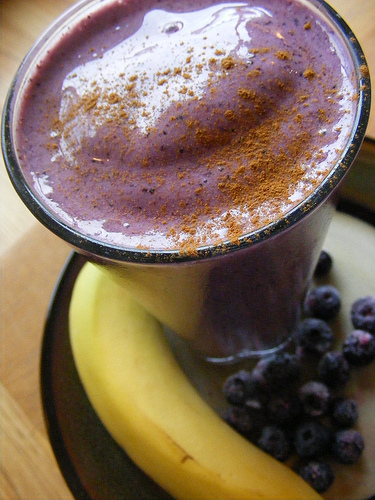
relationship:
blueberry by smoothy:
[299, 317, 337, 357] [17, 3, 355, 249]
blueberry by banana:
[299, 317, 337, 357] [67, 262, 331, 499]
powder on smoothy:
[198, 124, 301, 205] [17, 3, 355, 249]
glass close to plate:
[4, 3, 371, 363] [41, 133, 374, 498]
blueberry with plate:
[299, 317, 337, 357] [41, 133, 374, 498]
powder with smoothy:
[198, 124, 301, 205] [17, 3, 355, 249]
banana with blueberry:
[67, 262, 331, 499] [299, 317, 337, 357]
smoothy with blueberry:
[17, 3, 355, 249] [299, 317, 337, 357]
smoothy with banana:
[17, 3, 355, 249] [67, 262, 331, 499]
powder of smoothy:
[198, 124, 301, 205] [17, 3, 355, 249]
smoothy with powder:
[17, 3, 355, 249] [198, 124, 301, 205]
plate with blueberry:
[41, 133, 374, 498] [299, 317, 337, 357]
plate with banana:
[41, 133, 374, 498] [67, 262, 331, 499]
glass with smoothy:
[4, 3, 371, 363] [17, 3, 355, 249]